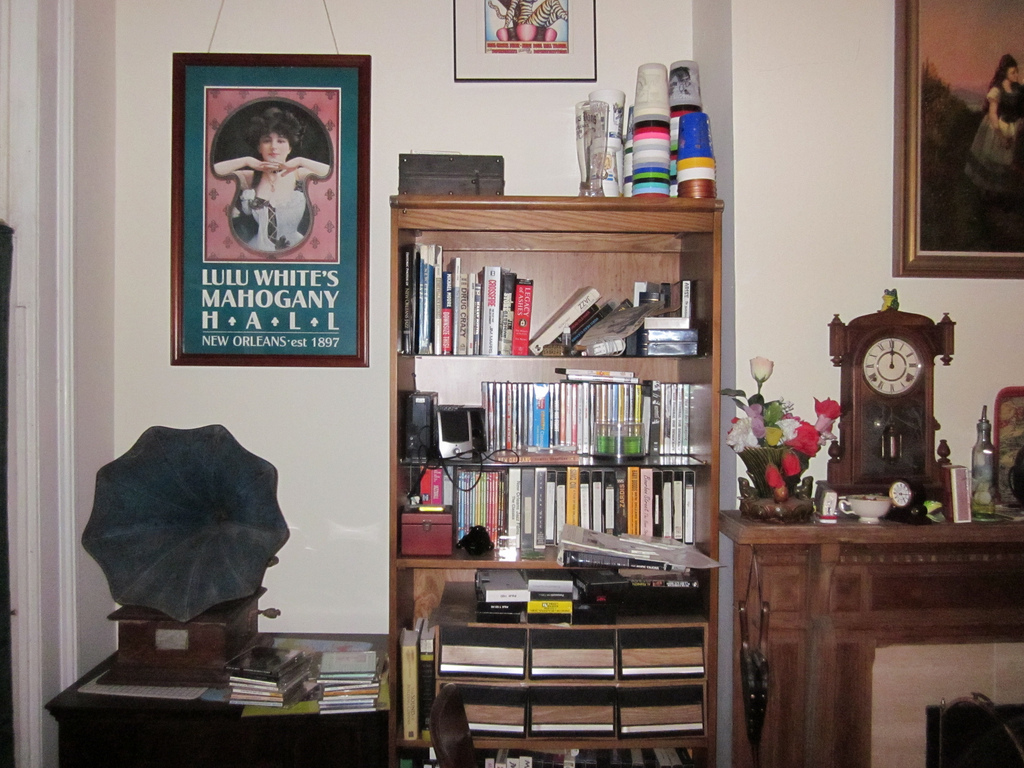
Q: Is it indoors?
A: Yes, it is indoors.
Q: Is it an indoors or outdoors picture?
A: It is indoors.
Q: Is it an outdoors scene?
A: No, it is indoors.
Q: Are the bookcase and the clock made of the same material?
A: Yes, both the bookcase and the clock are made of wood.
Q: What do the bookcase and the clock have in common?
A: The material, both the bookcase and the clock are wooden.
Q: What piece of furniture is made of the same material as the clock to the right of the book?
A: The bookcase is made of the same material as the clock.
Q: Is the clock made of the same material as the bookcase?
A: Yes, both the clock and the bookcase are made of wood.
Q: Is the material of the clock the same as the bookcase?
A: Yes, both the clock and the bookcase are made of wood.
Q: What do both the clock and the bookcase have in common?
A: The material, both the clock and the bookcase are wooden.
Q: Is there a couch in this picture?
A: No, there are no couches.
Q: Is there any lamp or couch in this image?
A: No, there are no couches or lamps.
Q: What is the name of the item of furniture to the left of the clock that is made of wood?
A: The piece of furniture is a shelf.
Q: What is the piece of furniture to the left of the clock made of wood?
A: The piece of furniture is a shelf.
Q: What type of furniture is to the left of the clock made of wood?
A: The piece of furniture is a shelf.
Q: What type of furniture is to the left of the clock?
A: The piece of furniture is a shelf.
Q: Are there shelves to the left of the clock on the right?
A: Yes, there is a shelf to the left of the clock.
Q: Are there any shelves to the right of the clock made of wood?
A: No, the shelf is to the left of the clock.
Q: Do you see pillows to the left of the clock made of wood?
A: No, there is a shelf to the left of the clock.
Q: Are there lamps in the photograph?
A: No, there are no lamps.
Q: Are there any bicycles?
A: No, there are no bicycles.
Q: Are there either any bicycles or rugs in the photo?
A: No, there are no bicycles or rugs.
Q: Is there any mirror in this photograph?
A: No, there are no mirrors.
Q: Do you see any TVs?
A: No, there are no tvs.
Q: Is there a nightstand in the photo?
A: No, there are no nightstands.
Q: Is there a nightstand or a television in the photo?
A: No, there are no nightstands or televisions.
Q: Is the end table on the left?
A: Yes, the end table is on the left of the image.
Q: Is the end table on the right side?
A: No, the end table is on the left of the image.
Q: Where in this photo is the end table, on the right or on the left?
A: The end table is on the left of the image.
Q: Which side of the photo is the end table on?
A: The end table is on the left of the image.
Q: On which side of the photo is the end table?
A: The end table is on the left of the image.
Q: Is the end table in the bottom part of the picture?
A: Yes, the end table is in the bottom of the image.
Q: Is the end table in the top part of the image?
A: No, the end table is in the bottom of the image.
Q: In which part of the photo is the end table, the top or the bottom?
A: The end table is in the bottom of the image.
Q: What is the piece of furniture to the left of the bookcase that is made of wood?
A: The piece of furniture is an end table.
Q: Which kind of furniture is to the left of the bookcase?
A: The piece of furniture is an end table.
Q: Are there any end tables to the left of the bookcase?
A: Yes, there is an end table to the left of the bookcase.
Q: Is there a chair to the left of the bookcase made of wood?
A: No, there is an end table to the left of the bookcase.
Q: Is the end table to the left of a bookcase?
A: Yes, the end table is to the left of a bookcase.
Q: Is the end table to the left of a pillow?
A: No, the end table is to the left of a bookcase.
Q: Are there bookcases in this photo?
A: Yes, there is a bookcase.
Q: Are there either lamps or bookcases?
A: Yes, there is a bookcase.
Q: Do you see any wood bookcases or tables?
A: Yes, there is a wood bookcase.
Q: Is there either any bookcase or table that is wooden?
A: Yes, the bookcase is wooden.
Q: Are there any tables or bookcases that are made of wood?
A: Yes, the bookcase is made of wood.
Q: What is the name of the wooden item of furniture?
A: The piece of furniture is a bookcase.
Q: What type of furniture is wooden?
A: The furniture is a bookcase.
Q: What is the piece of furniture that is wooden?
A: The piece of furniture is a bookcase.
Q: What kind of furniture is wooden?
A: The furniture is a bookcase.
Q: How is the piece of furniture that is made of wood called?
A: The piece of furniture is a bookcase.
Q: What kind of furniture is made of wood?
A: The furniture is a bookcase.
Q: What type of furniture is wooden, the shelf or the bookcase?
A: The bookcase is wooden.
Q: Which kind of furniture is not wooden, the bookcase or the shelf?
A: The shelf is not wooden.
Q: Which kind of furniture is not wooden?
A: The furniture is a shelf.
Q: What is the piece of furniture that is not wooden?
A: The piece of furniture is a shelf.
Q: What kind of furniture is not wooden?
A: The furniture is a shelf.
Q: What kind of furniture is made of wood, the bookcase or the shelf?
A: The bookcase is made of wood.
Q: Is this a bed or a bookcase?
A: This is a bookcase.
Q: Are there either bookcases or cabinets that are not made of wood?
A: No, there is a bookcase but it is made of wood.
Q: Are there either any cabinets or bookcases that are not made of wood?
A: No, there is a bookcase but it is made of wood.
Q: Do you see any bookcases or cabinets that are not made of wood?
A: No, there is a bookcase but it is made of wood.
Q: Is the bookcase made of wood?
A: Yes, the bookcase is made of wood.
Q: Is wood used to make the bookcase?
A: Yes, the bookcase is made of wood.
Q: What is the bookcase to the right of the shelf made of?
A: The bookcase is made of wood.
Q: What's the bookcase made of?
A: The bookcase is made of wood.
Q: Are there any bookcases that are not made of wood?
A: No, there is a bookcase but it is made of wood.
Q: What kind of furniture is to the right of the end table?
A: The piece of furniture is a bookcase.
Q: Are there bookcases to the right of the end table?
A: Yes, there is a bookcase to the right of the end table.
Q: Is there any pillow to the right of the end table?
A: No, there is a bookcase to the right of the end table.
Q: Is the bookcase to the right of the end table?
A: Yes, the bookcase is to the right of the end table.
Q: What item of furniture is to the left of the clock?
A: The piece of furniture is a bookcase.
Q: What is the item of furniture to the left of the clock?
A: The piece of furniture is a bookcase.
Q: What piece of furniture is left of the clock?
A: The piece of furniture is a bookcase.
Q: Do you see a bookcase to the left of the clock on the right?
A: Yes, there is a bookcase to the left of the clock.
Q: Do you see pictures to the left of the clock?
A: No, there is a bookcase to the left of the clock.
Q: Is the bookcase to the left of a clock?
A: Yes, the bookcase is to the left of a clock.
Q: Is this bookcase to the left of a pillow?
A: No, the bookcase is to the left of a clock.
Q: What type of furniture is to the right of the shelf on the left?
A: The piece of furniture is a bookcase.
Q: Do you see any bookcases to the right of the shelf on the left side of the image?
A: Yes, there is a bookcase to the right of the shelf.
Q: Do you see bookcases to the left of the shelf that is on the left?
A: No, the bookcase is to the right of the shelf.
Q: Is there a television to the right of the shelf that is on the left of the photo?
A: No, there is a bookcase to the right of the shelf.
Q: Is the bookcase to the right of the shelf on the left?
A: Yes, the bookcase is to the right of the shelf.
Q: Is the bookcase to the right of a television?
A: No, the bookcase is to the right of the shelf.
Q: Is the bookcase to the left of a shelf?
A: No, the bookcase is to the right of a shelf.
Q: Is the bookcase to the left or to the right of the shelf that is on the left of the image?
A: The bookcase is to the right of the shelf.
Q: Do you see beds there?
A: No, there are no beds.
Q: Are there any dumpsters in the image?
A: No, there are no dumpsters.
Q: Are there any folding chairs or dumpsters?
A: No, there are no dumpsters or folding chairs.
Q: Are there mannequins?
A: No, there are no mannequins.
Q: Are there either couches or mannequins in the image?
A: No, there are no mannequins or couches.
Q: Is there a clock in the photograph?
A: Yes, there is a clock.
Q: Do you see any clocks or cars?
A: Yes, there is a clock.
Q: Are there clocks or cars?
A: Yes, there is a clock.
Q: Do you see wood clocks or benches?
A: Yes, there is a wood clock.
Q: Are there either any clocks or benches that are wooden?
A: Yes, the clock is wooden.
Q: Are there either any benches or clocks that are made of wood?
A: Yes, the clock is made of wood.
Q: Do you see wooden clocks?
A: Yes, there is a wood clock.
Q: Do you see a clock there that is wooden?
A: Yes, there is a clock that is wooden.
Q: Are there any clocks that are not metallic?
A: Yes, there is a wooden clock.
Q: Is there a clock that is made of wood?
A: Yes, there is a clock that is made of wood.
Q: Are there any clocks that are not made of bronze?
A: Yes, there is a clock that is made of wood.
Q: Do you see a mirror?
A: No, there are no mirrors.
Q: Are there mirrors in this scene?
A: No, there are no mirrors.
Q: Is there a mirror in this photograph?
A: No, there are no mirrors.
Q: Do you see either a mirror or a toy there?
A: No, there are no mirrors or toys.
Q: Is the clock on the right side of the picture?
A: Yes, the clock is on the right of the image.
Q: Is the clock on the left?
A: No, the clock is on the right of the image.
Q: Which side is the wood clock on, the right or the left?
A: The clock is on the right of the image.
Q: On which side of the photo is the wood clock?
A: The clock is on the right of the image.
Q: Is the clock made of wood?
A: Yes, the clock is made of wood.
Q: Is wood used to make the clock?
A: Yes, the clock is made of wood.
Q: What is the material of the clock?
A: The clock is made of wood.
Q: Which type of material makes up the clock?
A: The clock is made of wood.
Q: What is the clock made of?
A: The clock is made of wood.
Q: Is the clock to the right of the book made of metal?
A: No, the clock is made of wood.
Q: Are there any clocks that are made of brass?
A: No, there is a clock but it is made of wood.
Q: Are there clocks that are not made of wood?
A: No, there is a clock but it is made of wood.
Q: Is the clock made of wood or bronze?
A: The clock is made of wood.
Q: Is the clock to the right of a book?
A: Yes, the clock is to the right of a book.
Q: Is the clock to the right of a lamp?
A: No, the clock is to the right of a book.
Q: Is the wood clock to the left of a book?
A: No, the clock is to the right of a book.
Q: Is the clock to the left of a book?
A: No, the clock is to the right of a book.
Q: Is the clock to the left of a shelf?
A: No, the clock is to the right of a shelf.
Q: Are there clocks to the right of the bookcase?
A: Yes, there is a clock to the right of the bookcase.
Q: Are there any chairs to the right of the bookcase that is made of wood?
A: No, there is a clock to the right of the bookcase.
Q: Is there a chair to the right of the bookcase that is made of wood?
A: No, there is a clock to the right of the bookcase.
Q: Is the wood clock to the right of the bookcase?
A: Yes, the clock is to the right of the bookcase.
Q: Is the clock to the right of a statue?
A: No, the clock is to the right of the bookcase.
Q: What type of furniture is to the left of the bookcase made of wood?
A: The piece of furniture is a shelf.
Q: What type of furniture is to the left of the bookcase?
A: The piece of furniture is a shelf.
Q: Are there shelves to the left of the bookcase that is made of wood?
A: Yes, there is a shelf to the left of the bookcase.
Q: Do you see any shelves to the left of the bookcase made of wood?
A: Yes, there is a shelf to the left of the bookcase.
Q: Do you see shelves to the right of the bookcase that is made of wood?
A: No, the shelf is to the left of the bookcase.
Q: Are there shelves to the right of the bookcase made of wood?
A: No, the shelf is to the left of the bookcase.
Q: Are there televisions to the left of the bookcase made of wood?
A: No, there is a shelf to the left of the bookcase.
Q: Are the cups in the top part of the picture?
A: Yes, the cups are in the top of the image.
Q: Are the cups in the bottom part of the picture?
A: No, the cups are in the top of the image.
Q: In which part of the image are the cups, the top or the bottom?
A: The cups are in the top of the image.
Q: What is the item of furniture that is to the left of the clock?
A: The piece of furniture is a shelf.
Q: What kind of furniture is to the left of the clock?
A: The piece of furniture is a shelf.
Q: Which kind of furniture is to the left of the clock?
A: The piece of furniture is a shelf.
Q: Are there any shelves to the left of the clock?
A: Yes, there is a shelf to the left of the clock.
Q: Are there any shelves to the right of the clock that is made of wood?
A: No, the shelf is to the left of the clock.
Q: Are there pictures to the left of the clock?
A: No, there is a shelf to the left of the clock.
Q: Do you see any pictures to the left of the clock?
A: No, there is a shelf to the left of the clock.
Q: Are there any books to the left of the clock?
A: Yes, there is a book to the left of the clock.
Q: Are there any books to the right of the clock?
A: No, the book is to the left of the clock.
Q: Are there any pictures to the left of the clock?
A: No, there is a book to the left of the clock.